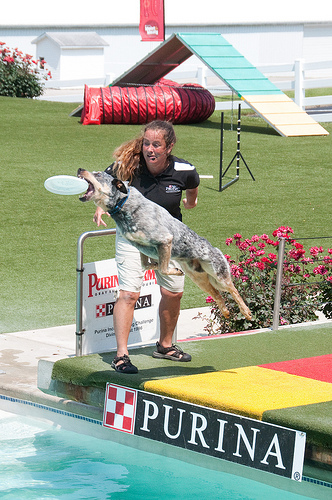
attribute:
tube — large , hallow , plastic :
[78, 77, 214, 127]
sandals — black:
[116, 355, 141, 375]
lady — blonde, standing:
[79, 113, 206, 372]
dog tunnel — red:
[80, 76, 215, 125]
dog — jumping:
[51, 151, 285, 318]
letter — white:
[111, 361, 289, 498]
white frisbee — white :
[43, 173, 91, 198]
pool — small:
[4, 411, 283, 499]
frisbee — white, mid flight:
[42, 174, 88, 194]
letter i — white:
[213, 418, 226, 455]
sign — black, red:
[106, 382, 318, 488]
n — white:
[234, 421, 259, 463]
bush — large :
[2, 35, 48, 103]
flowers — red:
[244, 233, 265, 264]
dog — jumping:
[38, 156, 221, 273]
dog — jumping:
[55, 166, 255, 331]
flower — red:
[191, 226, 330, 335]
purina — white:
[104, 297, 150, 316]